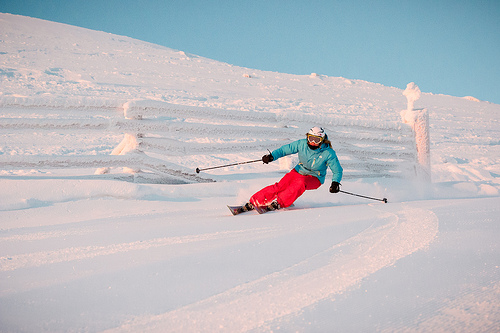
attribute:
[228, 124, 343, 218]
skiier — turning left, inclined, bent, leaning left, skiing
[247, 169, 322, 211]
pants — red, bright pink, pink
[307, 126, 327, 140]
helmet — white, blue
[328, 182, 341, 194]
glove — black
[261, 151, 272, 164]
glove — black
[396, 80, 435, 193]
pole — snow covered, ornate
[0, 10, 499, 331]
ground — snow covered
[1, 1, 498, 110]
sky — blue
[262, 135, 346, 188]
jacket — blue, aqua blue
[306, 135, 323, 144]
goggles — orange, white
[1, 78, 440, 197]
fence — white, snow covered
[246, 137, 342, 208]
snowsuit — blue, red